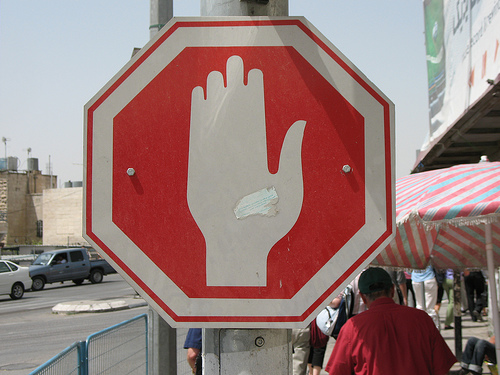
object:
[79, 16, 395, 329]
sign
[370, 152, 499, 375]
umbrella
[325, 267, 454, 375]
man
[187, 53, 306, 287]
hand